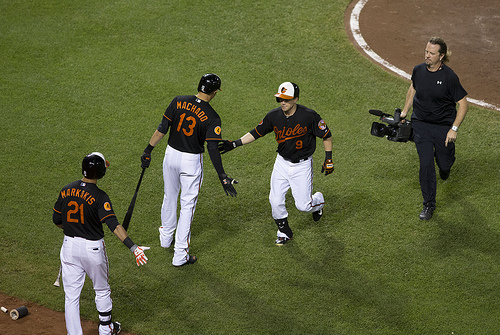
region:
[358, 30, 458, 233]
a man carrying a camera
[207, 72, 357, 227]
the player is wearing gloves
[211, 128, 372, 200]
the player is wearing gloves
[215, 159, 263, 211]
the player is wearing gloves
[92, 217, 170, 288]
the player is wearing gloves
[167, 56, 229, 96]
the helmet is black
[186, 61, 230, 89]
the helmet is black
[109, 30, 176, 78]
green turf on baseball field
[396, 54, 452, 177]
black outfit on camera man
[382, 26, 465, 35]
dirt mound on pitchers mound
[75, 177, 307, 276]
white pants on uniform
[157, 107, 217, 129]
number 13 on orange text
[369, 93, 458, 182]
black camera in hand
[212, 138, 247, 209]
black gloves on players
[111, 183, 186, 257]
bat in man's hand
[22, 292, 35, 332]
black item on floor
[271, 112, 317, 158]
orange text saying Orioles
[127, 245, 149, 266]
an orange and white baseball glove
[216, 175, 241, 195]
a black baseball glove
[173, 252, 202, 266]
a man's tennis shoe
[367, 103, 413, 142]
a large black camera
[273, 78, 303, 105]
a baseball cap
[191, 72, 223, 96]
a black helmet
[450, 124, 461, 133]
a man's wristwatch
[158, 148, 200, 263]
a man's white pants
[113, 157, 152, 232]
a black baseball bat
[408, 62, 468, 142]
a man's short sleeve shirt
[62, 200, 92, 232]
Team Player Number in Orange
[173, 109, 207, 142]
Team player number in Orange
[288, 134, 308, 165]
Team Player Number In Orange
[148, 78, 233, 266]
Black White and Orange Baseball Uniform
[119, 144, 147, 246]
Black Baseball Bat Facing Ground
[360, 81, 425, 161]
Large Black Television Camera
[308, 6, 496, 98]
Pitchers Mound With White Chalk Circle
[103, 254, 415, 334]
Players Shadows On The Field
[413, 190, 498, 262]
Camera Man Shadow On Field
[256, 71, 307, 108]
Official Team Baseball Hat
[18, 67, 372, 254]
Three baseball players wearing white pants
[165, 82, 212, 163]
The jersey is black with orange lettering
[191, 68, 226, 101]
The player is wearing a helmet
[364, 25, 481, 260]
Man in black carrying a camera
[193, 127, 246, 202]
This boy has a long black sleeve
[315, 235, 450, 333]
This is natural turf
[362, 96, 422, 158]
A large camera to film the game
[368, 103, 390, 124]
The microphone on the camera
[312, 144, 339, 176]
A batting glove that is black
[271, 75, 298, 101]
Baseball cap is black and white with an orange bill